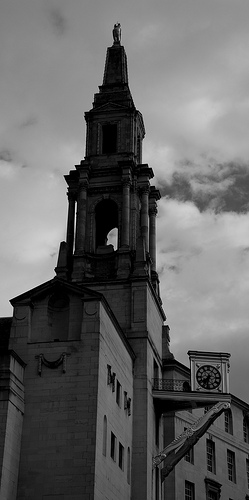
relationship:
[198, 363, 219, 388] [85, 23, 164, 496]
clock aside tower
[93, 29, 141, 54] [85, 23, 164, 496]
statue on tower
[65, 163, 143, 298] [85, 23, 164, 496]
columns surround tower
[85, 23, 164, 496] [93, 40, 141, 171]
tower contains parapets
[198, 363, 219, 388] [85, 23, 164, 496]
clock on side of tower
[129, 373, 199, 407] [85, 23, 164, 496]
balcony on tower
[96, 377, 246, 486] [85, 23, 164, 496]
windows on tower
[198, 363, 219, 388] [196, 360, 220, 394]
clock has roman numerals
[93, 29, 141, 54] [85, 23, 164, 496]
statue atop tower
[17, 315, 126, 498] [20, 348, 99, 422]
wall contains brick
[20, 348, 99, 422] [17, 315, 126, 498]
brick on wall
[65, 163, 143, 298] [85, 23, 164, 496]
columns on tower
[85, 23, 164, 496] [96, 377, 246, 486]
tower has windows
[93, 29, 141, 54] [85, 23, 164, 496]
statue on top of tower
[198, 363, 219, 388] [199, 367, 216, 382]
clock has face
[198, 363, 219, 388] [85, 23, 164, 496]
clock on side of a tower